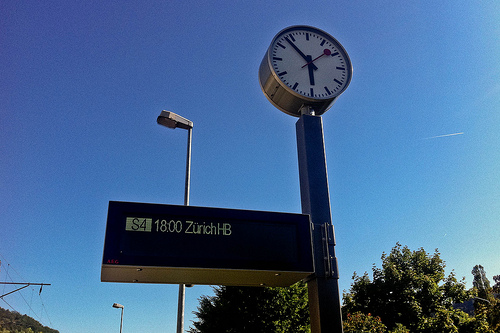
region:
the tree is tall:
[405, 274, 419, 304]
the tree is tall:
[415, 267, 427, 297]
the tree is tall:
[393, 283, 404, 303]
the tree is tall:
[394, 280, 410, 304]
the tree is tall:
[422, 265, 430, 292]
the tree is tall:
[414, 283, 424, 298]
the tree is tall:
[404, 278, 412, 296]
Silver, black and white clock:
[254, 12, 363, 119]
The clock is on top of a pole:
[248, 19, 375, 311]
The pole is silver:
[282, 98, 361, 317]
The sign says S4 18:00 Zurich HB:
[80, 186, 269, 266]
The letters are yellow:
[118, 204, 257, 257]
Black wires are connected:
[1, 251, 76, 324]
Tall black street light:
[141, 103, 208, 325]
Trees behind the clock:
[166, 243, 489, 325]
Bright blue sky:
[25, 11, 165, 133]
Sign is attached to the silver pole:
[83, 172, 370, 313]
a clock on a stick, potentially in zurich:
[252, 18, 369, 332]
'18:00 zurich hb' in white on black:
[151, 214, 234, 239]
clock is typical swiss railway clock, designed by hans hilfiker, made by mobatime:
[252, 18, 361, 125]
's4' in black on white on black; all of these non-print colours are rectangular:
[101, 201, 306, 276]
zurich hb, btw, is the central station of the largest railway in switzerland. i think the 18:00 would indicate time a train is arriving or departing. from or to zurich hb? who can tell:
[151, 211, 233, 242]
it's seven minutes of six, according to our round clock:
[248, 20, 358, 118]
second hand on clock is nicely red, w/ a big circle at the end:
[295, 42, 335, 70]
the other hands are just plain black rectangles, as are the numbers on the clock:
[252, 20, 357, 126]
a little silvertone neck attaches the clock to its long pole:
[295, 103, 318, 118]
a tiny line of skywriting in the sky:
[407, 120, 473, 153]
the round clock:
[258, 22, 352, 108]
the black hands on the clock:
[284, 36, 329, 91]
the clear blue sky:
[23, 7, 221, 100]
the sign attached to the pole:
[101, 197, 330, 281]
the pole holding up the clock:
[293, 108, 345, 331]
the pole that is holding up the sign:
[294, 114, 341, 331]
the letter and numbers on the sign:
[124, 212, 234, 237]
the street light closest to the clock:
[157, 104, 192, 331]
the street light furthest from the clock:
[108, 299, 123, 331]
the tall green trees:
[344, 237, 498, 327]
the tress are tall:
[388, 285, 404, 305]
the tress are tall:
[419, 303, 432, 324]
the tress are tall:
[417, 304, 427, 328]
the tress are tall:
[390, 291, 401, 316]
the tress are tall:
[394, 277, 406, 311]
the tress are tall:
[376, 277, 384, 309]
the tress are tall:
[381, 289, 395, 313]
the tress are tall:
[414, 274, 419, 286]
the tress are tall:
[393, 294, 403, 306]